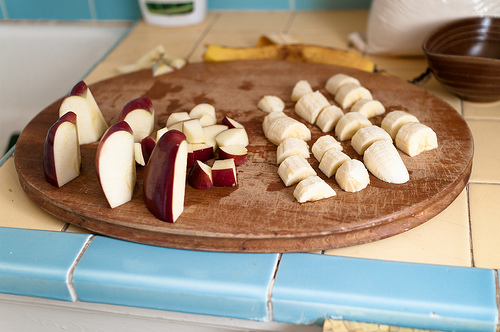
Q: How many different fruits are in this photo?
A: Two.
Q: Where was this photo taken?
A: A kitchen countertop.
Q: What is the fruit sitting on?
A: A wooden serving platter.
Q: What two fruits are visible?
A: Apple and banana.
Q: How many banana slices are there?
A: 20.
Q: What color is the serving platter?
A: Brown.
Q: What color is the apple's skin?
A: Red.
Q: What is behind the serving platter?
A: A banana peel.